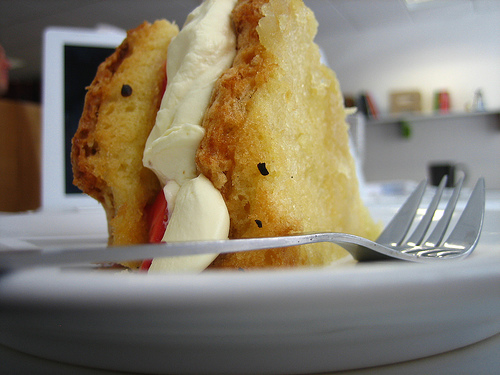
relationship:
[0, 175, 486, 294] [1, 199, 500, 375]
fork on plate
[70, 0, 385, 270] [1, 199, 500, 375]
food on plate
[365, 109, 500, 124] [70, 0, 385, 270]
shelf behind food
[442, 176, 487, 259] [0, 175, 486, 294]
prong on fork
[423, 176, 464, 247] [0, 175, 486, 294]
prong on fork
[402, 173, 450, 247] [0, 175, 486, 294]
prong on fork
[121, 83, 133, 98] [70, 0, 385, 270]
burnt area on food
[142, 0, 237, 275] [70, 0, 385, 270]
cream in food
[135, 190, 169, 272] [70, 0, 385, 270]
tomato in food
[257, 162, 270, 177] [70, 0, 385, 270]
burnt area on food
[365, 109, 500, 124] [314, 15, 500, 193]
shelf on wall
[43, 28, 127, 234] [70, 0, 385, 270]
laptop behind food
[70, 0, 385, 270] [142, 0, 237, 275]
food has cream